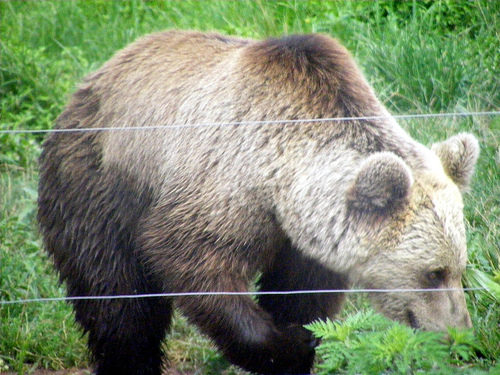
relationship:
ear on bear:
[350, 150, 413, 210] [34, 31, 480, 363]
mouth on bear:
[396, 303, 425, 330] [2, 20, 491, 368]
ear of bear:
[350, 148, 413, 207] [34, 31, 480, 363]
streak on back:
[238, 33, 376, 145] [60, 21, 365, 176]